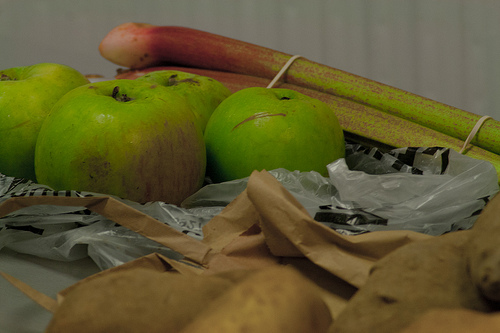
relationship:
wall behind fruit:
[1, 0, 500, 123] [97, 23, 500, 152]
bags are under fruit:
[1, 146, 499, 258] [97, 23, 500, 152]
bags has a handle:
[1, 146, 499, 258] [1, 191, 207, 307]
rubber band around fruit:
[264, 54, 300, 89] [97, 23, 500, 152]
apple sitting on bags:
[202, 88, 349, 177] [1, 146, 499, 258]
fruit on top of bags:
[97, 23, 500, 152] [1, 146, 499, 258]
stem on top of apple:
[110, 83, 123, 102] [32, 81, 208, 207]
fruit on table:
[97, 23, 500, 152] [1, 139, 497, 331]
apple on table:
[202, 88, 349, 177] [1, 139, 497, 331]